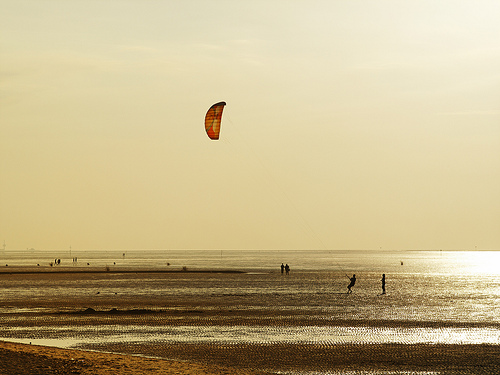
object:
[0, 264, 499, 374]
beach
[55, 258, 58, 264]
people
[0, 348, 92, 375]
shadow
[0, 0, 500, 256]
sky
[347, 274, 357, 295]
people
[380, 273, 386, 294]
people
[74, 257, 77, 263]
people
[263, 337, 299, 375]
ground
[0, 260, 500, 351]
shallow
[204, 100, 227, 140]
design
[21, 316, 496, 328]
wave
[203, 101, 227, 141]
kite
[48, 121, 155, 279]
string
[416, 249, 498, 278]
sun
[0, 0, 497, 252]
clouds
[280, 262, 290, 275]
two people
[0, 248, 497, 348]
water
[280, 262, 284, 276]
people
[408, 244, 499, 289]
suns reflection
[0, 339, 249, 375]
sand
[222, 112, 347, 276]
string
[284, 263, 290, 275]
people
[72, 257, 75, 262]
people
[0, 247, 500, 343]
ocean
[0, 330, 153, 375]
ground